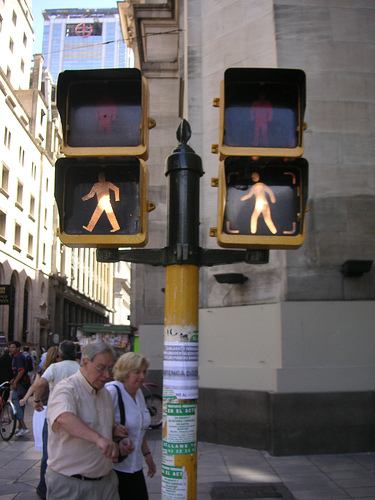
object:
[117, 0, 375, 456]
building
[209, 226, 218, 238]
clamp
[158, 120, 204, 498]
metal pole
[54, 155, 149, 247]
sign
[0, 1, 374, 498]
city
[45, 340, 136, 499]
man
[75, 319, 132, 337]
newstand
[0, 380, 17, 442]
bike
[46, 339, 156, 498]
couple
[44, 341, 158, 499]
couple walking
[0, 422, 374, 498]
sidewalk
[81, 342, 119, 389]
head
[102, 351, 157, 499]
woman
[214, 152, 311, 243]
sign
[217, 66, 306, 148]
sign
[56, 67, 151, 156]
sign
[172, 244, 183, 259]
bolt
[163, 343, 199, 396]
stickers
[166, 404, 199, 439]
stickers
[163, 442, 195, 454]
stickers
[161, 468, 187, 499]
stickers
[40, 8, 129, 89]
skyscraper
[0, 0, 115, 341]
building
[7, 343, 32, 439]
man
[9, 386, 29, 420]
shorts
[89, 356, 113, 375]
eye glass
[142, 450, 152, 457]
wrist watch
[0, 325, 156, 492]
business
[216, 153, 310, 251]
signal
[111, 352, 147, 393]
head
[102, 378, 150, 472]
shirt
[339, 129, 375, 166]
blocks